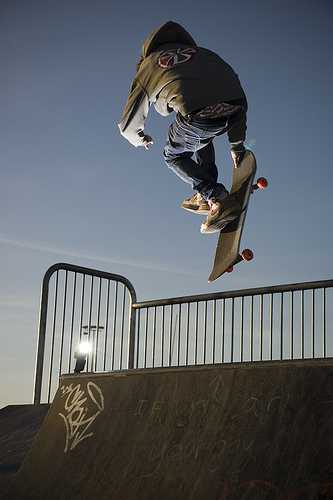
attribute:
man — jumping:
[109, 21, 246, 230]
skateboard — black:
[208, 133, 263, 287]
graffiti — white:
[50, 382, 298, 485]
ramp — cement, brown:
[12, 364, 330, 499]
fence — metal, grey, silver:
[27, 262, 332, 374]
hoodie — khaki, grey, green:
[116, 17, 245, 153]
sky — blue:
[11, 15, 111, 192]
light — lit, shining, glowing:
[60, 337, 102, 377]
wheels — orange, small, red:
[241, 175, 268, 265]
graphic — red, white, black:
[146, 45, 205, 69]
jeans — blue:
[164, 106, 243, 201]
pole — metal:
[131, 273, 332, 315]